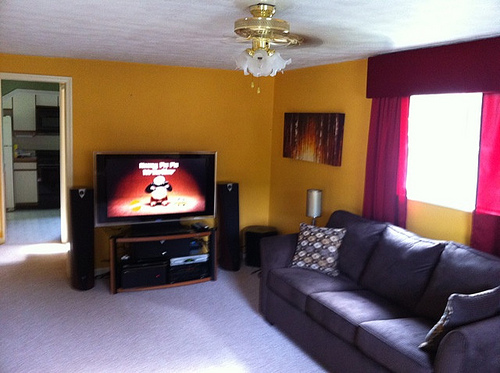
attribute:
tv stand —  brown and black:
[79, 99, 251, 309]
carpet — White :
[1, 255, 336, 371]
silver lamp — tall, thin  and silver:
[300, 186, 323, 218]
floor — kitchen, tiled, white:
[12, 207, 39, 232]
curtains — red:
[358, 34, 498, 258]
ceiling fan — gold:
[166, 4, 395, 97]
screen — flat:
[86, 153, 208, 223]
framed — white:
[55, 162, 65, 274]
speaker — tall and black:
[225, 160, 236, 256]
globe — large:
[227, 40, 297, 81]